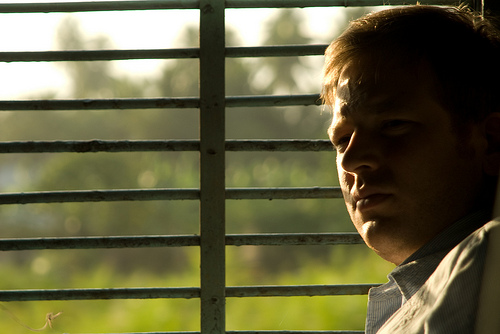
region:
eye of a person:
[324, 134, 360, 156]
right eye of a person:
[322, 129, 356, 153]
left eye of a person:
[372, 111, 424, 144]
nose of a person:
[335, 146, 384, 178]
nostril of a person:
[352, 159, 373, 180]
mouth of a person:
[329, 175, 404, 214]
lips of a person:
[342, 183, 401, 216]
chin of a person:
[350, 215, 405, 260]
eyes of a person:
[308, 103, 432, 160]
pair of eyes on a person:
[316, 106, 423, 151]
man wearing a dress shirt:
[351, 250, 487, 302]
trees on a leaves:
[51, 43, 261, 235]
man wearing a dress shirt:
[333, 224, 465, 330]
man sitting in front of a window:
[296, 29, 426, 269]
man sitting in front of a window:
[292, 15, 488, 309]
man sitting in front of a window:
[287, 41, 439, 328]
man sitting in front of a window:
[294, 30, 484, 330]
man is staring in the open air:
[297, 81, 477, 296]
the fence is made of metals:
[173, 56, 301, 253]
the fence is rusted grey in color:
[155, 47, 297, 331]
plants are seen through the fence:
[80, 43, 271, 256]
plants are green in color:
[38, 86, 265, 288]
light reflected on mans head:
[301, 63, 368, 240]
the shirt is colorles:
[363, 267, 458, 333]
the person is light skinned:
[315, 144, 376, 211]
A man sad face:
[302, 14, 486, 291]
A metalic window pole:
[10, 282, 197, 313]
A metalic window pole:
[232, 280, 352, 308]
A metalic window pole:
[247, 218, 353, 273]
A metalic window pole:
[17, 221, 177, 268]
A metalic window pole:
[15, 170, 204, 211]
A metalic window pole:
[17, 128, 169, 173]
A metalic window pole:
[18, 90, 173, 123]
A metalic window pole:
[22, 40, 139, 72]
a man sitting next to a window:
[301, 9, 498, 291]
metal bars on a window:
[73, 32, 193, 298]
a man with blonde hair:
[303, 4, 489, 189]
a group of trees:
[59, 28, 317, 211]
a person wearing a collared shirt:
[351, 243, 498, 327]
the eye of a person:
[328, 121, 356, 148]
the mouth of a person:
[350, 183, 390, 215]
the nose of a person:
[337, 131, 383, 173]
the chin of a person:
[359, 215, 406, 252]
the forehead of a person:
[320, 60, 409, 108]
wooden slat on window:
[226, 43, 323, 55]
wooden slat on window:
[226, 93, 329, 108]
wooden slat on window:
[226, 136, 336, 151]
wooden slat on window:
[225, 185, 346, 198]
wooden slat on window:
[226, 232, 361, 244]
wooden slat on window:
[226, 283, 380, 297]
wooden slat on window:
[1, 283, 196, 297]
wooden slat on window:
[3, 191, 200, 203]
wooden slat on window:
[4, 139, 197, 154]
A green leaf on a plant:
[71, 163, 73, 168]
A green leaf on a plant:
[97, 168, 102, 170]